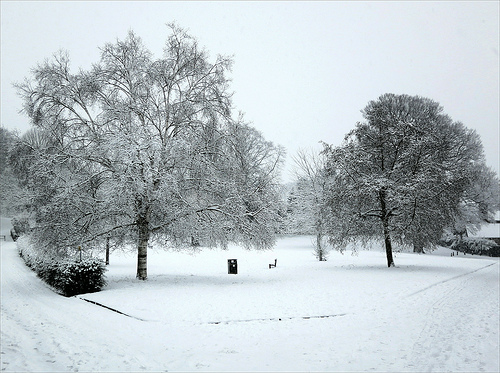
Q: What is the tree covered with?
A: Snow.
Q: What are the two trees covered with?
A: Snow.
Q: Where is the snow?
A: On the ground.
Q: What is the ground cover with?
A: Snow.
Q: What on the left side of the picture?
A: A tree.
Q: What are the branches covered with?
A: Snow.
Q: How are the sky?
A: Cloudy.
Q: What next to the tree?
A: Bush.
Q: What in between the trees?
A: Garbage can.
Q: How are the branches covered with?
A: Snow flakes.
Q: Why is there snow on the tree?
A: It is winter time.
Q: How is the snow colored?
A: White.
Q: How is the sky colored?
A: White.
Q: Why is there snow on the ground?
A: It was snowing.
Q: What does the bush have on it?
A: Snow.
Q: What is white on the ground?
A: Snow.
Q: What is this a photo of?
A: Wintertime.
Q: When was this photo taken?
A: In the daytime.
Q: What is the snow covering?
A: Trees.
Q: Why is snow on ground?
A: Its cold.